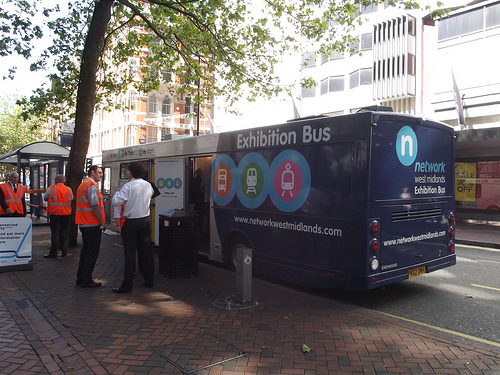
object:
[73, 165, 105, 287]
man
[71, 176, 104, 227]
vest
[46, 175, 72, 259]
man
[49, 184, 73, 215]
vest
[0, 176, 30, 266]
man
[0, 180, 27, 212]
vest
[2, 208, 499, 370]
sidewalk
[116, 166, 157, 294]
man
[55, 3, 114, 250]
tree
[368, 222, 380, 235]
light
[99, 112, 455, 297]
bus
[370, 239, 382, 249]
light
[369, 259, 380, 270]
light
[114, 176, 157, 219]
shirt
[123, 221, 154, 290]
pants